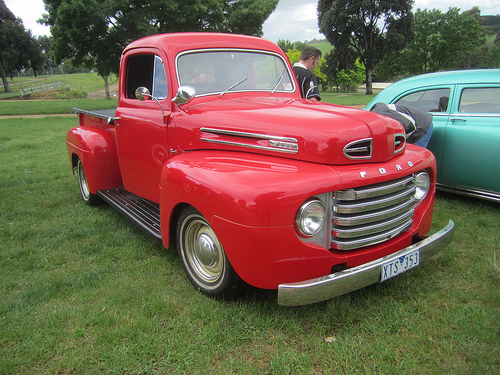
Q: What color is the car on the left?
A: Red.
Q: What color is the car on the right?
A: Green.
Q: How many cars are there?
A: Two.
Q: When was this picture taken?
A: Daytime.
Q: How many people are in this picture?
A: One.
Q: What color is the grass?
A: Green.